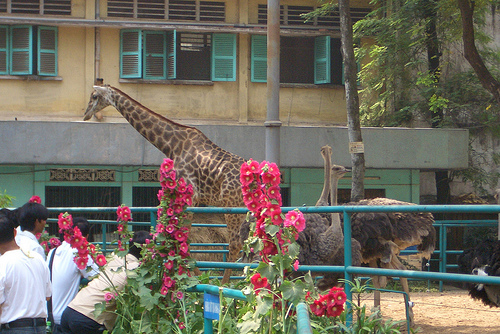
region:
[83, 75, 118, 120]
the head of a giraffe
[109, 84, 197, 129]
the mane of a giraffe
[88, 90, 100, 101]
the eye of a giraffe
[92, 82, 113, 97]
the ear of a giraffe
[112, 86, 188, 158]
the neck of a giraffe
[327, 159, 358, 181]
the head of an ostrich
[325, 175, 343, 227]
the neck of an ostrich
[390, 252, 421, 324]
the leg of an ostrich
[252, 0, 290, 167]
a gray metal pole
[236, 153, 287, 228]
pink flowers on the plant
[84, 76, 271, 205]
The giraffe is brown and tan.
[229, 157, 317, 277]
The flowers are pink.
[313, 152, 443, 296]
The ostrich is brown.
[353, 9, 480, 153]
The leafs are green.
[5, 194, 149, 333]
The people are wearing white shirts.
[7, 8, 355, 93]
The windows have teal shutters.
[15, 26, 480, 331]
They are outside.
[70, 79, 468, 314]
The animals are in a cage.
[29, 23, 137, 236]
The buildings are tan and blue.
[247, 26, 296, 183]
The pole is metal.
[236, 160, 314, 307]
pretty pink flowers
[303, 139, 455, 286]
2 big ostriches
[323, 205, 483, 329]
blue metal fence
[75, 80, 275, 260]
a tall giraffe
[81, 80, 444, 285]
animals in a zoo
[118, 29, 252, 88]
blue shutters on windows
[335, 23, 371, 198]
grey tree trunk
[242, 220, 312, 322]
green leaves with flowers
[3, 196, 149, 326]
a group of men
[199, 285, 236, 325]
a blue sign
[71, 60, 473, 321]
a giraffe with ostrich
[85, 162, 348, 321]
the flowers are pink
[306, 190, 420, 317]
the fence is blue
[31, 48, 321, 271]
the giraffe is tall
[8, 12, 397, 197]
the wall is dirty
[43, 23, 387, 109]
the windows are open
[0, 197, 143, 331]
the people are watching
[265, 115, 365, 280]
ostrich has long neck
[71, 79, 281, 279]
the giraffe is brown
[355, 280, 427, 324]
the ground is made of sand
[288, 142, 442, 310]
2 ostriches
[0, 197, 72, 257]
people with black hair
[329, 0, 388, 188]
a gray tree trunk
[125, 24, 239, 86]
blue window shutters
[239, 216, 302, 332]
green leaves on flowers